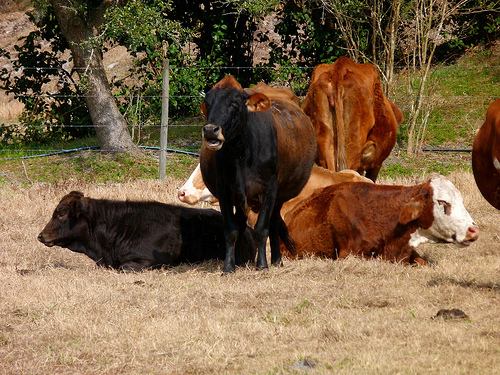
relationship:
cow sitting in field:
[292, 175, 469, 265] [14, 169, 472, 373]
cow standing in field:
[298, 55, 404, 184] [8, 152, 498, 372]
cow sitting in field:
[298, 55, 404, 184] [5, 122, 476, 371]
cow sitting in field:
[38, 190, 242, 272] [9, 84, 499, 373]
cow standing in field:
[298, 55, 404, 184] [5, 122, 476, 371]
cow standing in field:
[468, 97, 500, 213] [13, 128, 498, 366]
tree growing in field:
[32, 14, 139, 155] [6, 68, 469, 373]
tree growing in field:
[0, 0, 149, 163] [5, 122, 476, 371]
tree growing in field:
[0, 0, 149, 163] [9, 84, 499, 373]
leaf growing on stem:
[41, 92, 78, 122] [44, 80, 81, 117]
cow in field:
[298, 55, 404, 184] [9, 84, 499, 373]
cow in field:
[298, 55, 404, 184] [8, 152, 498, 372]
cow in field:
[468, 101, 483, 221] [5, 122, 476, 371]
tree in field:
[0, 0, 149, 163] [8, 152, 498, 372]